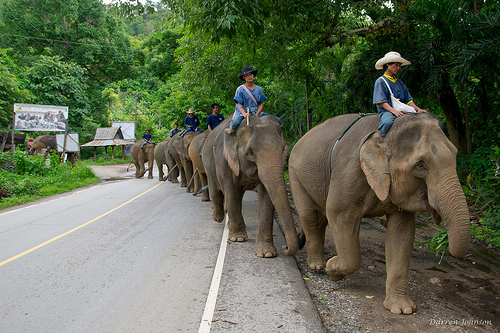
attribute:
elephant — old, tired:
[106, 43, 489, 309]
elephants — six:
[125, 108, 478, 320]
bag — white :
[387, 92, 422, 121]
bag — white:
[379, 77, 416, 113]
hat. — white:
[373, 44, 407, 67]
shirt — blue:
[205, 115, 230, 132]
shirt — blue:
[370, 72, 407, 104]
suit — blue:
[227, 83, 269, 125]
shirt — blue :
[367, 74, 420, 116]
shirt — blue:
[369, 73, 417, 120]